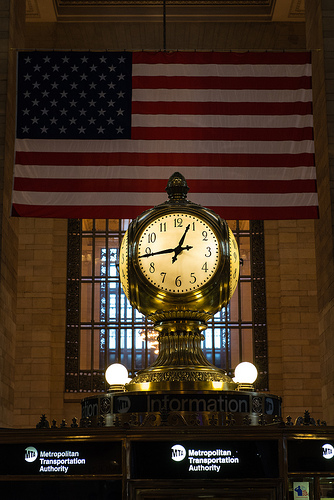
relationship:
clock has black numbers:
[104, 166, 251, 333] [130, 209, 231, 301]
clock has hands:
[104, 166, 251, 333] [136, 242, 195, 260]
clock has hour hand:
[104, 166, 251, 333] [170, 218, 195, 261]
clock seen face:
[104, 166, 251, 333] [130, 209, 231, 301]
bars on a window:
[72, 218, 134, 361] [60, 212, 278, 381]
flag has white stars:
[8, 41, 332, 228] [17, 42, 138, 141]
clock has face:
[104, 166, 251, 333] [130, 209, 231, 301]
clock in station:
[104, 166, 251, 333] [6, 4, 332, 496]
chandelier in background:
[28, 404, 86, 429] [1, 402, 85, 431]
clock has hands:
[104, 166, 251, 333] [136, 221, 195, 265]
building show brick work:
[6, 4, 332, 496] [6, 217, 68, 400]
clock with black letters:
[104, 166, 251, 333] [130, 209, 231, 301]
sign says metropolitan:
[162, 439, 249, 480] [187, 444, 234, 461]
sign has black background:
[162, 439, 249, 480] [127, 442, 277, 478]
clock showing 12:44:
[104, 166, 251, 333] [136, 221, 195, 265]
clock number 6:
[104, 166, 251, 333] [169, 269, 187, 291]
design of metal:
[27, 389, 333, 437] [12, 407, 330, 432]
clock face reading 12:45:
[104, 166, 251, 333] [136, 221, 195, 265]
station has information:
[6, 4, 332, 496] [143, 382, 256, 415]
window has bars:
[60, 212, 278, 381] [72, 218, 134, 361]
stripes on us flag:
[231, 143, 269, 188] [8, 41, 332, 228]